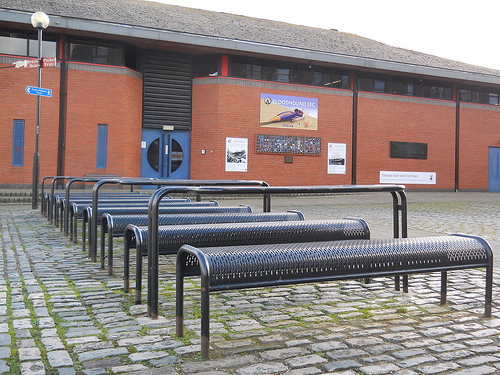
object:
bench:
[175, 232, 496, 336]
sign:
[259, 93, 318, 131]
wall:
[201, 75, 428, 190]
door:
[136, 126, 193, 195]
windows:
[244, 59, 265, 80]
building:
[0, 0, 500, 201]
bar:
[136, 182, 416, 315]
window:
[93, 121, 110, 170]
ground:
[13, 233, 81, 368]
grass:
[41, 293, 63, 325]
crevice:
[46, 283, 64, 350]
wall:
[79, 68, 127, 123]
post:
[25, 86, 52, 99]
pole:
[29, 28, 42, 211]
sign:
[11, 56, 58, 69]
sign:
[327, 141, 347, 175]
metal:
[121, 184, 414, 323]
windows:
[146, 133, 184, 175]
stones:
[274, 320, 326, 358]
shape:
[487, 145, 500, 192]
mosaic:
[254, 134, 323, 157]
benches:
[121, 214, 378, 307]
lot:
[41, 170, 500, 346]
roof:
[0, 0, 500, 88]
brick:
[216, 89, 252, 127]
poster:
[224, 136, 249, 172]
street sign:
[24, 85, 53, 99]